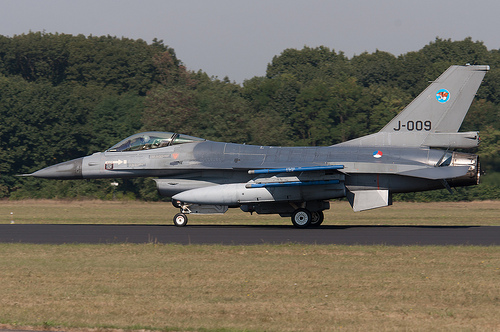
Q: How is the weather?
A: It is clear.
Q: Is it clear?
A: Yes, it is clear.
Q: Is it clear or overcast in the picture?
A: It is clear.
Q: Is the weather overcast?
A: No, it is clear.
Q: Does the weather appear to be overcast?
A: No, it is clear.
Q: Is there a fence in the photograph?
A: No, there are no fences.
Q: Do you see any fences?
A: No, there are no fences.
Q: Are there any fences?
A: No, there are no fences.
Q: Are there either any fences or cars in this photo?
A: No, there are no fences or cars.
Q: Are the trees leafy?
A: Yes, the trees are leafy.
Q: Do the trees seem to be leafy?
A: Yes, the trees are leafy.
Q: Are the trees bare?
A: No, the trees are leafy.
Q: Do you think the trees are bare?
A: No, the trees are leafy.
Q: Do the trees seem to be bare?
A: No, the trees are leafy.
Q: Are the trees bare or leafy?
A: The trees are leafy.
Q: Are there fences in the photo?
A: No, there are no fences.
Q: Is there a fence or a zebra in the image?
A: No, there are no fences or zebras.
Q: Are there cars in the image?
A: No, there are no cars.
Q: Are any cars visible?
A: No, there are no cars.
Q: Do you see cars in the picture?
A: No, there are no cars.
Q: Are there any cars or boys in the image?
A: No, there are no cars or boys.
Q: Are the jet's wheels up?
A: No, the wheels are down.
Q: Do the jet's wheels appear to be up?
A: No, the wheels are down.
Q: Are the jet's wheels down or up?
A: The wheels are down.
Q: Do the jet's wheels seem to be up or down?
A: The wheels are down.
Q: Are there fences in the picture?
A: No, there are no fences.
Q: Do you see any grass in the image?
A: Yes, there is grass.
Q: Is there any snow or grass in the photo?
A: Yes, there is grass.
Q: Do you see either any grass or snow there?
A: Yes, there is grass.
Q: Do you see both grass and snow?
A: No, there is grass but no snow.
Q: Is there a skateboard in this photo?
A: No, there are no skateboards.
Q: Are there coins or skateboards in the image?
A: No, there are no skateboards or coins.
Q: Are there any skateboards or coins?
A: No, there are no skateboards or coins.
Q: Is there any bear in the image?
A: No, there are no bears.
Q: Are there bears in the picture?
A: No, there are no bears.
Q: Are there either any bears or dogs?
A: No, there are no bears or dogs.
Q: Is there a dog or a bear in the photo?
A: No, there are no bears or dogs.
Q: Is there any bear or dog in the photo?
A: No, there are no bears or dogs.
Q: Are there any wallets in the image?
A: No, there are no wallets.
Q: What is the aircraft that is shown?
A: The aircraft is a jet.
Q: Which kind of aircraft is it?
A: The aircraft is a jet.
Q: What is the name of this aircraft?
A: This is a jet.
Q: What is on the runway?
A: The jet is on the runway.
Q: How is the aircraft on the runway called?
A: The aircraft is a jet.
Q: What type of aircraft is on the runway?
A: The aircraft is a jet.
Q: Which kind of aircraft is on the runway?
A: The aircraft is a jet.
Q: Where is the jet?
A: The jet is on the runway.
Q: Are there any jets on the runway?
A: Yes, there is a jet on the runway.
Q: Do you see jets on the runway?
A: Yes, there is a jet on the runway.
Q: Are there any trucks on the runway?
A: No, there is a jet on the runway.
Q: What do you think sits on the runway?
A: The jet sits on the runway.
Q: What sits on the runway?
A: The jet sits on the runway.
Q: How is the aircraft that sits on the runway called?
A: The aircraft is a jet.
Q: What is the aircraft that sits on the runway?
A: The aircraft is a jet.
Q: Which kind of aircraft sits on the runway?
A: The aircraft is a jet.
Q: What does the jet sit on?
A: The jet sits on the runway.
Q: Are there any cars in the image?
A: No, there are no cars.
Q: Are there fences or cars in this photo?
A: No, there are no cars or fences.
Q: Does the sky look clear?
A: Yes, the sky is clear.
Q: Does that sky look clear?
A: Yes, the sky is clear.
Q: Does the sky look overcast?
A: No, the sky is clear.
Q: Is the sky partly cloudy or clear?
A: The sky is clear.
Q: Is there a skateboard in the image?
A: No, there are no skateboards.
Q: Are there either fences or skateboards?
A: No, there are no skateboards or fences.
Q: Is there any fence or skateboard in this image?
A: No, there are no skateboards or fences.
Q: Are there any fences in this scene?
A: No, there are no fences.